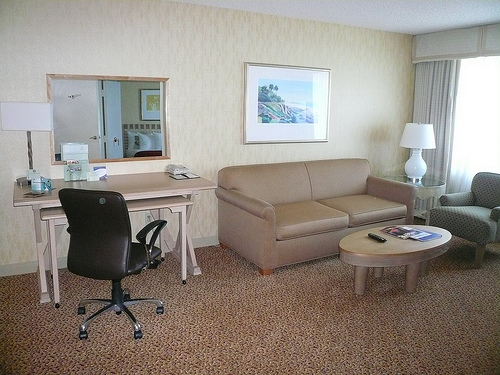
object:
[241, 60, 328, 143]
artwork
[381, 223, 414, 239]
books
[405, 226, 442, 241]
books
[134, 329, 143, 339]
black wheel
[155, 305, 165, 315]
black wheel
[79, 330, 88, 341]
black wheel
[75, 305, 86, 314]
black wheel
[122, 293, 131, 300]
black wheel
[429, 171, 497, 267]
chair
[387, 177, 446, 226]
table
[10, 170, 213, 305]
desk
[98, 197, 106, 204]
circle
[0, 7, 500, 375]
room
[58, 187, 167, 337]
chair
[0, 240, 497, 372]
floor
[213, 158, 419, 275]
leather couch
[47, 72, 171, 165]
framed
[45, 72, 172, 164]
mirror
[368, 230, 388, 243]
remote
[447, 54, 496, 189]
window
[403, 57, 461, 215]
curtain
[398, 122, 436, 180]
lamp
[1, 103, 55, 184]
lamp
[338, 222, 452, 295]
table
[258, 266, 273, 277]
leg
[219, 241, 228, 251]
leg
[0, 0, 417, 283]
wall